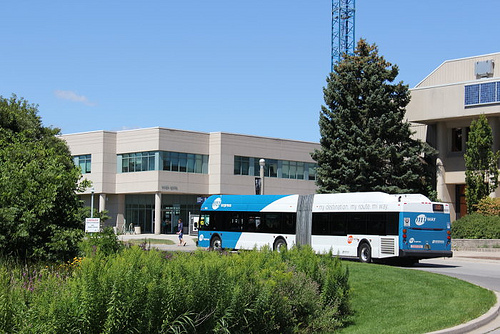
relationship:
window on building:
[235, 152, 243, 177] [62, 127, 327, 245]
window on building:
[184, 153, 195, 170] [62, 127, 327, 245]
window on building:
[146, 152, 154, 169] [62, 127, 327, 245]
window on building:
[123, 151, 130, 171] [62, 127, 327, 245]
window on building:
[290, 158, 305, 178] [62, 127, 327, 245]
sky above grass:
[33, 11, 313, 113] [330, 254, 471, 331]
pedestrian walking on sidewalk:
[174, 215, 188, 250] [112, 225, 202, 251]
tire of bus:
[356, 237, 371, 262] [185, 176, 453, 278]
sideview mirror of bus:
[194, 221, 199, 228] [192, 190, 453, 261]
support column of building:
[153, 190, 160, 231] [30, 107, 354, 257]